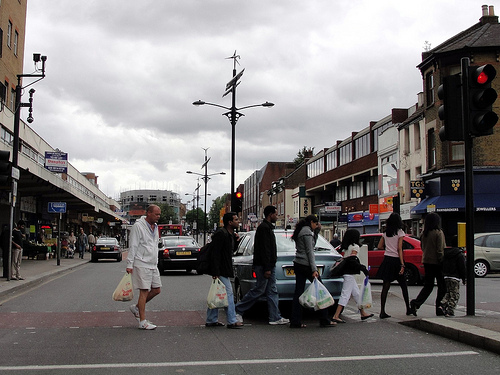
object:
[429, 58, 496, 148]
traffic light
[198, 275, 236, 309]
plastic bag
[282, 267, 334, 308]
plastic bag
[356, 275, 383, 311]
plastic bag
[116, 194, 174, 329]
guy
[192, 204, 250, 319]
guy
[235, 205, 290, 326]
guy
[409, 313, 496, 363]
sidewalk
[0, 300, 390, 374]
crosswalk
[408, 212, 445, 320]
people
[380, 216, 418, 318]
people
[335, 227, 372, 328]
people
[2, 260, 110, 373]
street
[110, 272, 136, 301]
bag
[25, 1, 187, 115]
sky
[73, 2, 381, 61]
cloud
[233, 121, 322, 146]
cloud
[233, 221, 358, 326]
car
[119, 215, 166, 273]
shirt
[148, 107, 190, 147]
clouds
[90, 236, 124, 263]
car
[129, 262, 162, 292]
shorts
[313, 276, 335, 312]
bags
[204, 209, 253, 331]
boy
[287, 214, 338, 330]
lady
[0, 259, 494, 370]
road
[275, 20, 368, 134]
cloud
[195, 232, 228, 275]
bag